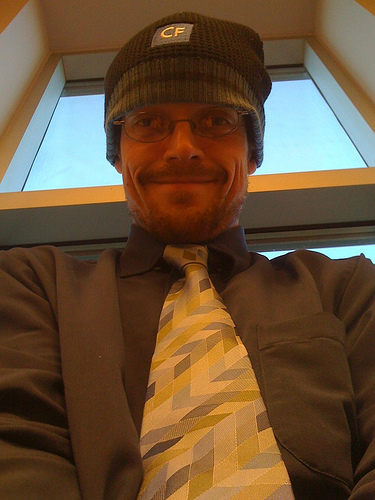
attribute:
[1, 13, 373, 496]
man — smiling, looking down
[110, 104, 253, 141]
glasses — eye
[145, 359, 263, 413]
design — chevron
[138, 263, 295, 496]
tie — multicolored, gray , white , yellow, multi-colored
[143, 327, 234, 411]
design — chevron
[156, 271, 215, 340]
design — chevron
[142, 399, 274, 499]
design — chevron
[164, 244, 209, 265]
design — chevron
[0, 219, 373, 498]
shirt — brown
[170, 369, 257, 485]
design — chevron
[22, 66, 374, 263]
window — behind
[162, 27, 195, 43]
cf — written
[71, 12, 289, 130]
hat — knit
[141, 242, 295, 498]
tie — multicolored